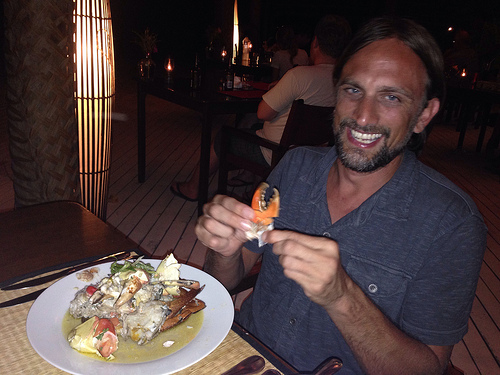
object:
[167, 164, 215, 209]
sandals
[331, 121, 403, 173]
beard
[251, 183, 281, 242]
claw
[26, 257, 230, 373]
plate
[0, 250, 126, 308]
utensils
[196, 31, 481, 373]
man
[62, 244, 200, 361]
meal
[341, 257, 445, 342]
button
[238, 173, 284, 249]
seafood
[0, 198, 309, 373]
table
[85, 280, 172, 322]
seafood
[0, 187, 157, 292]
folder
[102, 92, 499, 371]
floor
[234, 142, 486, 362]
blue shirt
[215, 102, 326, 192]
chair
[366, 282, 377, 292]
shirt button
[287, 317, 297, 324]
shirt button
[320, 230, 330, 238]
shirt button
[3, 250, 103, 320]
utensil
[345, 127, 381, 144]
smile